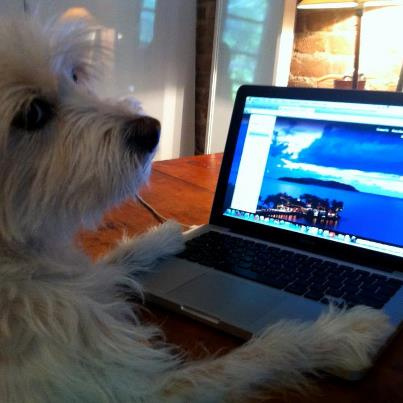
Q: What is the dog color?
A: White.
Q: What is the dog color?
A: White.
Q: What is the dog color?
A: White.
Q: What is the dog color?
A: White.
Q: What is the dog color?
A: White.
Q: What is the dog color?
A: White.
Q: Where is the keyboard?
A: Laptop.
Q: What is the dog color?
A: White.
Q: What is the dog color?
A: White.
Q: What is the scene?
A: Water.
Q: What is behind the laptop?
A: Lamp.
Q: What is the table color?
A: Brown.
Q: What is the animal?
A: Dog.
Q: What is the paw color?
A: White.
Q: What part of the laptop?
A: Keyboard.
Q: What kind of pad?
A: Mousepad.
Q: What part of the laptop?
A: Screen.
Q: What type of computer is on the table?
A: A laptop.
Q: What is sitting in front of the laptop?
A: A large dog.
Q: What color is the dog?
A: White.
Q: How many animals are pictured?
A: 1.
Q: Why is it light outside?
A: Sunny.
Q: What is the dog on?
A: Computer.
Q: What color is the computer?
A: Gray.